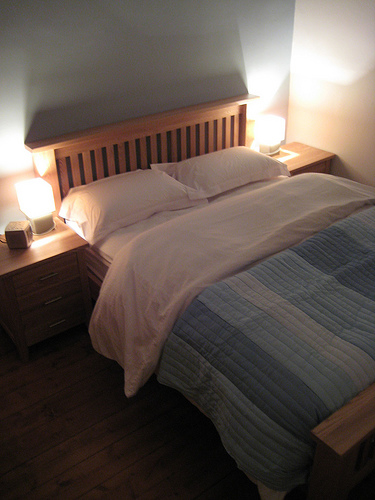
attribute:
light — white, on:
[13, 176, 60, 232]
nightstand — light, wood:
[0, 214, 92, 361]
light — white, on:
[256, 110, 285, 157]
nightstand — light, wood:
[269, 141, 335, 174]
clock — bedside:
[5, 220, 34, 247]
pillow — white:
[58, 168, 207, 247]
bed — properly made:
[27, 90, 374, 500]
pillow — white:
[150, 144, 292, 200]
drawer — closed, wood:
[25, 305, 87, 346]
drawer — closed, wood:
[20, 273, 89, 324]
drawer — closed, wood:
[12, 251, 84, 295]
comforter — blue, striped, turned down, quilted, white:
[89, 173, 375, 490]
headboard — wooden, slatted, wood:
[23, 94, 261, 224]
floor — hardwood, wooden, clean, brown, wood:
[0, 323, 265, 497]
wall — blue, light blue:
[0, 0, 300, 236]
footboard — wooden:
[302, 382, 374, 498]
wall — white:
[286, 1, 373, 188]